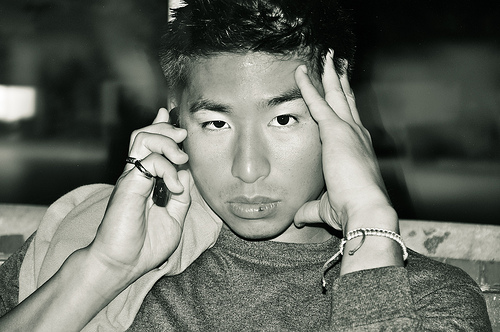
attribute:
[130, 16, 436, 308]
boy — asian, sitting, talking, listening, tan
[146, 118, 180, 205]
phone — black, small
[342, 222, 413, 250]
bracelet — white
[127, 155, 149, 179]
ring — gold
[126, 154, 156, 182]
rings — gold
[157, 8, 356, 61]
hair — short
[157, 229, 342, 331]
sweater — black